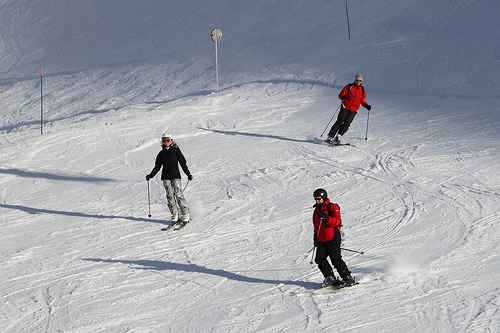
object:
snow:
[0, 0, 500, 333]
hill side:
[0, 0, 140, 331]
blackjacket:
[149, 142, 191, 181]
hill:
[0, 0, 499, 144]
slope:
[351, 139, 500, 333]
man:
[324, 74, 373, 144]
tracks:
[110, 289, 172, 307]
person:
[144, 132, 195, 223]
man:
[309, 187, 358, 288]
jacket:
[311, 198, 344, 245]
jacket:
[338, 84, 369, 112]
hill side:
[327, 0, 500, 333]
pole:
[39, 67, 45, 135]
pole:
[344, 0, 352, 40]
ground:
[0, 0, 500, 333]